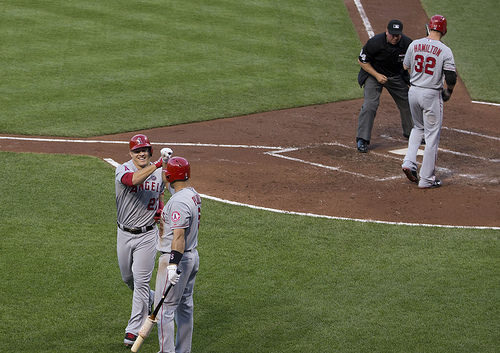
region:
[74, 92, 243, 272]
two players on field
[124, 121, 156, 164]
helmet on the player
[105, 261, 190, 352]
bat in man's hand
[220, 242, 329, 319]
green grass on ground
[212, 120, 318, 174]
white line on ground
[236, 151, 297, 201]
dirt on the ground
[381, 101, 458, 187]
two legs of the man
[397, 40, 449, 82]
number 32 on jersey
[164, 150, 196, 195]
Man wearing red helmet.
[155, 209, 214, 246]
Man wearing gray jersey.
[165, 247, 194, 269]
Black band around man's wrist.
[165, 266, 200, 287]
Man wearing white glove.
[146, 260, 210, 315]
Man holding baseball bat.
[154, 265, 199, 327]
Man wearing gray pants.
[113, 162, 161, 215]
Man wearing gray jersey.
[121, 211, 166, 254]
Man wearing black belt.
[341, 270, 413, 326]
the grass on the baseball field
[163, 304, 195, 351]
grey pants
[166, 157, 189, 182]
a red helmet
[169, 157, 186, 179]
a helmet the player is wearing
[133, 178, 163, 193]
logo on the jersey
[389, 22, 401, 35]
the umpire is wearing a hat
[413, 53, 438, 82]
a number on the jersey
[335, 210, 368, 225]
a white line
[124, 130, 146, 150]
helmet on player's head.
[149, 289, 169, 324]
bat in player's hand.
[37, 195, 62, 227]
grass in foul territory.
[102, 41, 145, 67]
grass on the infield.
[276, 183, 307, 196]
dirt on the field.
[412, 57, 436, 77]
number on the jersey.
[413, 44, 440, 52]
name on the jersey.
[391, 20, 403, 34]
cap on umpire's head.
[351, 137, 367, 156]
shoe on umpire's foot.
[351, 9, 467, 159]
player next to plate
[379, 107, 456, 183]
legs of the player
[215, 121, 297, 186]
white line on ground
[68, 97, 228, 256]
two baseball players in photo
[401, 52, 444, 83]
number on back of jersey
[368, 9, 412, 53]
head of a man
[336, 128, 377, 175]
foot of the man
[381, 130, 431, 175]
plate under the umpire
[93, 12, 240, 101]
green grass on field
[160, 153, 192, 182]
helmet is red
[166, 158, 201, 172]
helmet on the head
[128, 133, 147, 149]
the helmet is red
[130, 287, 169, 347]
bat in the hand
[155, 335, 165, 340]
the stripe is red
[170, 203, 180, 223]
patch on the sleeve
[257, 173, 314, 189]
dirt on the field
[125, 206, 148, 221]
the shirt is grey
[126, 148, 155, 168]
head of the man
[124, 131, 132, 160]
a red hard helmet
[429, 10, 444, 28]
a red hard helmet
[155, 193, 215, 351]
a man holding a bat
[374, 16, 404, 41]
a black hat on the head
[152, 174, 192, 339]
a man in uniform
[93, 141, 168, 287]
a man in uniform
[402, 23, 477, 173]
a man in uniform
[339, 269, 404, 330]
green field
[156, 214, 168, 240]
dirt on the uniform